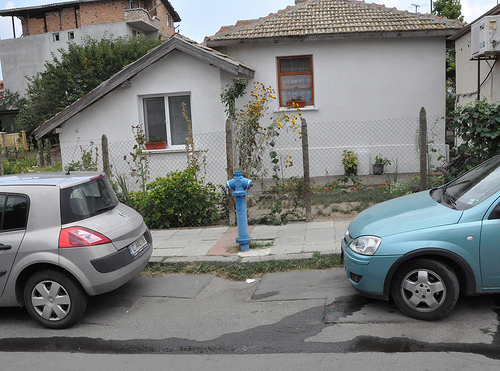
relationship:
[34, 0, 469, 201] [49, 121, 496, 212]
grey house behind metallic fence.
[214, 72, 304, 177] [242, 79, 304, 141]
plant with flowers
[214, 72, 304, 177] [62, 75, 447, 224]
plant in front yard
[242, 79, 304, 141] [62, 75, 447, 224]
flowers in front yard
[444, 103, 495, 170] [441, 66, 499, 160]
plant growing along fence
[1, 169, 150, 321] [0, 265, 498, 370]
car in street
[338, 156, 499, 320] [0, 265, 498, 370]
blue car in street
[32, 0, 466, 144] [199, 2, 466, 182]
roof on house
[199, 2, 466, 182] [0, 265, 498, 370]
house next to street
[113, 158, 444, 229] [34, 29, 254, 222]
front yard of grey house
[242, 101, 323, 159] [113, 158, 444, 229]
flowers in front yard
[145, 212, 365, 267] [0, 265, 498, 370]
sidewalk next to street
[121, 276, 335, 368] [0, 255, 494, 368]
pavement on street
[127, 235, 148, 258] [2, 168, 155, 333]
license plate on car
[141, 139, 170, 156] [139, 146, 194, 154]
box on window sill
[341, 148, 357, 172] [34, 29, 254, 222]
green plant on grey house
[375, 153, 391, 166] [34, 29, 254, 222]
green plant on grey house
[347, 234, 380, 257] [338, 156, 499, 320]
headlight on blue car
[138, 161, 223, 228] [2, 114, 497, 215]
green plants in front of fence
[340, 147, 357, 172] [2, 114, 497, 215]
green plant in front of fence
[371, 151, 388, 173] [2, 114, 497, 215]
green plant in front of fence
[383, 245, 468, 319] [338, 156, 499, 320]
wheel of blue car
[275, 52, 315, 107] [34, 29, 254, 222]
window on grey house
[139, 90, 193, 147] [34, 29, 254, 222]
window on grey house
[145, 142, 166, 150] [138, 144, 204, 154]
box on window sill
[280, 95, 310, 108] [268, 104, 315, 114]
flower pot on window sill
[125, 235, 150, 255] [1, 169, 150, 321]
license plate on car